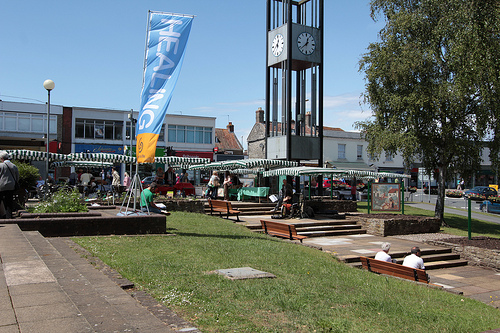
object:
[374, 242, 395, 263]
female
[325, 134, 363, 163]
white wall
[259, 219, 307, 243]
bench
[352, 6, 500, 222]
tree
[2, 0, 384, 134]
blue sky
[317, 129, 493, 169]
building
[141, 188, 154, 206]
green shirt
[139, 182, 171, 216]
person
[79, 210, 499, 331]
area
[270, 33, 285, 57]
clock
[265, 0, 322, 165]
tower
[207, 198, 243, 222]
bench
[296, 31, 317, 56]
clock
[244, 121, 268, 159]
wall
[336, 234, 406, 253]
concrete sidewalk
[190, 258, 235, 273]
grass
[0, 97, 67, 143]
buildings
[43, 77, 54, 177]
light post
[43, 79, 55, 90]
globe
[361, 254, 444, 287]
bench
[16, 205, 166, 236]
stoop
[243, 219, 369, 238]
steps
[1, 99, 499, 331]
park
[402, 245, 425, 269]
gentleman